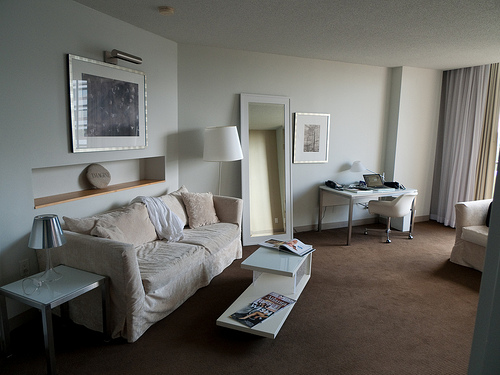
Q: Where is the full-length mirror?
A: Leaning against the far wall.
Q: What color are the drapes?
A: White and tan.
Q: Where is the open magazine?
A: On the coffee table.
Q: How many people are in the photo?
A: None.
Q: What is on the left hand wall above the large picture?
A: A light.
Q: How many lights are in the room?
A: Three.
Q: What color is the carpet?
A: Dark brown.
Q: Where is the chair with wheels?
A: In front of the desk against the far wall.